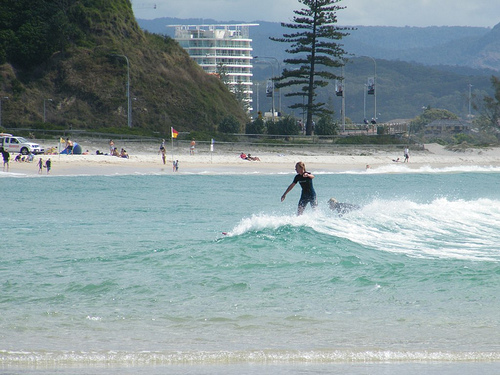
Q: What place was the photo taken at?
A: It was taken at the ocean.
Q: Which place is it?
A: It is an ocean.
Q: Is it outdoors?
A: Yes, it is outdoors.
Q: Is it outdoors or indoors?
A: It is outdoors.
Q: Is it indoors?
A: No, it is outdoors.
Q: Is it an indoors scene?
A: No, it is outdoors.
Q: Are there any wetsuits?
A: Yes, there is a wetsuit.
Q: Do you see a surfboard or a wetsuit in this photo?
A: Yes, there is a wetsuit.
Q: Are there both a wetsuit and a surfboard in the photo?
A: Yes, there are both a wetsuit and a surfboard.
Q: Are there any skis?
A: No, there are no skis.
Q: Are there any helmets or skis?
A: No, there are no skis or helmets.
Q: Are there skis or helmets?
A: No, there are no skis or helmets.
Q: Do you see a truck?
A: Yes, there is a truck.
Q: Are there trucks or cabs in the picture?
A: Yes, there is a truck.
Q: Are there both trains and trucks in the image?
A: No, there is a truck but no trains.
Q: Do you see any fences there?
A: No, there are no fences.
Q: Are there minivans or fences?
A: No, there are no fences or minivans.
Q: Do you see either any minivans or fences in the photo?
A: No, there are no fences or minivans.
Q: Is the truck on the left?
A: Yes, the truck is on the left of the image.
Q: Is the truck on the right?
A: No, the truck is on the left of the image.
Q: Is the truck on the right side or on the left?
A: The truck is on the left of the image.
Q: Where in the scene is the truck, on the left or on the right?
A: The truck is on the left of the image.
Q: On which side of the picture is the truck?
A: The truck is on the left of the image.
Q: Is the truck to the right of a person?
A: No, the truck is to the left of a person.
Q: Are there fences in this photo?
A: No, there are no fences.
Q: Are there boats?
A: No, there are no boats.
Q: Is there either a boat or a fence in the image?
A: No, there are no boats or fences.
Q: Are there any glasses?
A: No, there are no glasses.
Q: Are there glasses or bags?
A: No, there are no glasses or bags.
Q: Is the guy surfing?
A: Yes, the guy is surfing.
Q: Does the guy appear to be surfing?
A: Yes, the guy is surfing.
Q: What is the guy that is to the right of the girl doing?
A: The guy is surfing.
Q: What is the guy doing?
A: The guy is surfing.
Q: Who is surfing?
A: The guy is surfing.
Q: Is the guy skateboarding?
A: No, the guy is surfing.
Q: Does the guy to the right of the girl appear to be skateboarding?
A: No, the guy is surfing.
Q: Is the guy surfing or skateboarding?
A: The guy is surfing.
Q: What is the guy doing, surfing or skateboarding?
A: The guy is surfing.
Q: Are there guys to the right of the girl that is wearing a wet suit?
A: Yes, there is a guy to the right of the girl.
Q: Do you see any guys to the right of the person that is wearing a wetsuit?
A: Yes, there is a guy to the right of the girl.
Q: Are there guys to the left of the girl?
A: No, the guy is to the right of the girl.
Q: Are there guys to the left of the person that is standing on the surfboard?
A: No, the guy is to the right of the girl.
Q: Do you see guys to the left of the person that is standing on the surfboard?
A: No, the guy is to the right of the girl.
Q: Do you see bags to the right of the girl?
A: No, there is a guy to the right of the girl.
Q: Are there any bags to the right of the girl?
A: No, there is a guy to the right of the girl.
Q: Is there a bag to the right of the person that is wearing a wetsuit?
A: No, there is a guy to the right of the girl.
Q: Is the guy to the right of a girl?
A: Yes, the guy is to the right of a girl.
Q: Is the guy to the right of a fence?
A: No, the guy is to the right of a girl.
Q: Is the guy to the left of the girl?
A: No, the guy is to the right of the girl.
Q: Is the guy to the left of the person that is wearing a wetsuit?
A: No, the guy is to the right of the girl.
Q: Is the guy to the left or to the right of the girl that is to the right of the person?
A: The guy is to the right of the girl.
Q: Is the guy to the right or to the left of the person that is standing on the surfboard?
A: The guy is to the right of the girl.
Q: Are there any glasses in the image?
A: No, there are no glasses.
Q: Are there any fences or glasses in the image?
A: No, there are no glasses or fences.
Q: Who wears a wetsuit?
A: The girl wears a wetsuit.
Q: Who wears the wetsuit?
A: The girl wears a wetsuit.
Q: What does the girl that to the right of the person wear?
A: The girl wears a wetsuit.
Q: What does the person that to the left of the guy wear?
A: The girl wears a wetsuit.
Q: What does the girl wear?
A: The girl wears a wetsuit.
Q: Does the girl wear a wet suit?
A: Yes, the girl wears a wet suit.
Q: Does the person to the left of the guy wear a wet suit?
A: Yes, the girl wears a wet suit.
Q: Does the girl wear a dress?
A: No, the girl wears a wet suit.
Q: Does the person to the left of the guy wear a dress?
A: No, the girl wears a wet suit.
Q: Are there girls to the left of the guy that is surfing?
A: Yes, there is a girl to the left of the guy.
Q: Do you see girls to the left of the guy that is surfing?
A: Yes, there is a girl to the left of the guy.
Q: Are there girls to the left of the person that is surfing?
A: Yes, there is a girl to the left of the guy.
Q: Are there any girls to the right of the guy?
A: No, the girl is to the left of the guy.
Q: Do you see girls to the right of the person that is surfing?
A: No, the girl is to the left of the guy.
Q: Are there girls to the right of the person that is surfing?
A: No, the girl is to the left of the guy.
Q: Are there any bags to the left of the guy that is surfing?
A: No, there is a girl to the left of the guy.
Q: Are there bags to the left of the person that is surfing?
A: No, there is a girl to the left of the guy.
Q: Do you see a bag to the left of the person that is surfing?
A: No, there is a girl to the left of the guy.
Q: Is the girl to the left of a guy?
A: Yes, the girl is to the left of a guy.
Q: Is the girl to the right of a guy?
A: No, the girl is to the left of a guy.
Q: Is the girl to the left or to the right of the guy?
A: The girl is to the left of the guy.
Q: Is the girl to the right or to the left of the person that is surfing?
A: The girl is to the left of the guy.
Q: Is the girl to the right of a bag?
A: No, the girl is to the right of a person.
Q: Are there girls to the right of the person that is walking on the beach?
A: Yes, there is a girl to the right of the person.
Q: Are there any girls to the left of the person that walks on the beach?
A: No, the girl is to the right of the person.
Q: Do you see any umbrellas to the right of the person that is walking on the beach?
A: No, there is a girl to the right of the person.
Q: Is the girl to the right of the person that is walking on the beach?
A: Yes, the girl is to the right of the person.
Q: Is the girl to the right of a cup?
A: No, the girl is to the right of the person.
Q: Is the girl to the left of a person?
A: No, the girl is to the right of a person.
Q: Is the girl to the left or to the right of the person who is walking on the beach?
A: The girl is to the right of the person.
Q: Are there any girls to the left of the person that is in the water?
A: Yes, there is a girl to the left of the person.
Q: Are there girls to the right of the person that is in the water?
A: No, the girl is to the left of the person.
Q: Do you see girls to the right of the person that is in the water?
A: No, the girl is to the left of the person.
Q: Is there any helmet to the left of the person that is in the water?
A: No, there is a girl to the left of the person.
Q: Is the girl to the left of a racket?
A: No, the girl is to the left of a person.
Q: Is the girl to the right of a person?
A: No, the girl is to the left of a person.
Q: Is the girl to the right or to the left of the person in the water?
A: The girl is to the left of the person.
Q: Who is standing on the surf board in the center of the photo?
A: The girl is standing on the surfboard.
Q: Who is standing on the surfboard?
A: The girl is standing on the surfboard.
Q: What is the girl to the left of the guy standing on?
A: The girl is standing on the surf board.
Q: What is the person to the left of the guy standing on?
A: The girl is standing on the surf board.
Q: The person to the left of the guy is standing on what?
A: The girl is standing on the surf board.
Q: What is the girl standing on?
A: The girl is standing on the surf board.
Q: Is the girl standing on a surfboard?
A: Yes, the girl is standing on a surfboard.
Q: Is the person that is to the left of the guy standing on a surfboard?
A: Yes, the girl is standing on a surfboard.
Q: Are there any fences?
A: No, there are no fences.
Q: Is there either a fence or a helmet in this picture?
A: No, there are no fences or helmets.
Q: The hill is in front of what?
A: The hill is in front of the building.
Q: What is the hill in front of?
A: The hill is in front of the building.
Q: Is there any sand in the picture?
A: Yes, there is sand.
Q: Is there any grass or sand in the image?
A: Yes, there is sand.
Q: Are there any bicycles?
A: No, there are no bicycles.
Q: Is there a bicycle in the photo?
A: No, there are no bicycles.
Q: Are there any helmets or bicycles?
A: No, there are no bicycles or helmets.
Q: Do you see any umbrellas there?
A: No, there are no umbrellas.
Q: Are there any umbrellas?
A: No, there are no umbrellas.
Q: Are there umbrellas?
A: No, there are no umbrellas.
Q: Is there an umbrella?
A: No, there are no umbrellas.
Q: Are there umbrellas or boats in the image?
A: No, there are no umbrellas or boats.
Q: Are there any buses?
A: No, there are no buses.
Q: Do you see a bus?
A: No, there are no buses.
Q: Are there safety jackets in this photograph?
A: No, there are no safety jackets.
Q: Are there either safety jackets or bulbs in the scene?
A: No, there are no safety jackets or bulbs.